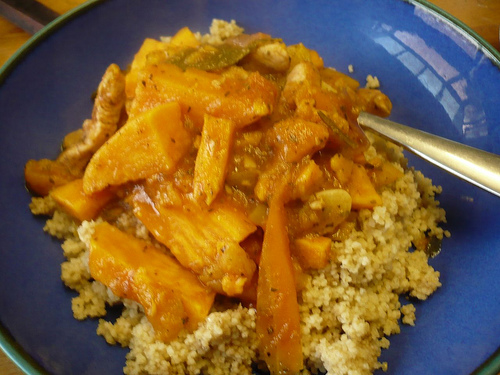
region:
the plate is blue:
[1, 0, 498, 372]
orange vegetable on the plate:
[38, 42, 398, 369]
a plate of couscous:
[3, 0, 499, 372]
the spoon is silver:
[363, 115, 498, 195]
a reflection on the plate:
[383, 23, 481, 136]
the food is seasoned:
[41, 19, 446, 371]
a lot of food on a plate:
[3, 0, 498, 372]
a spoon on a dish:
[352, 105, 494, 193]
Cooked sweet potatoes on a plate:
[31, 33, 408, 349]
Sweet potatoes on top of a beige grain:
[50, 21, 452, 374]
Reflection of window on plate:
[350, 7, 497, 146]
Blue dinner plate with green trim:
[0, 0, 494, 372]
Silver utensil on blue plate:
[341, 105, 498, 242]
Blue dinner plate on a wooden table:
[1, 0, 493, 371]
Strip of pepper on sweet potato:
[316, 109, 356, 153]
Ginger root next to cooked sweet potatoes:
[24, 67, 134, 185]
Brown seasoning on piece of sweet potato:
[260, 282, 284, 370]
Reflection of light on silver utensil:
[396, 128, 498, 193]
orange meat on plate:
[79, 25, 339, 295]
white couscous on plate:
[285, 195, 452, 357]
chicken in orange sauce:
[157, 72, 310, 232]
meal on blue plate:
[77, 60, 479, 350]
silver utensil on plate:
[362, 104, 499, 203]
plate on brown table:
[20, 20, 465, 327]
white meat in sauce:
[91, 77, 271, 271]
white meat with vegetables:
[53, 46, 410, 276]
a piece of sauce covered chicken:
[82, 220, 209, 320]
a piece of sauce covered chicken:
[133, 185, 248, 293]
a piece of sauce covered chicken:
[52, 180, 111, 219]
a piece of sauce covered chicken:
[82, 111, 193, 186]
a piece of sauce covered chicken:
[191, 111, 233, 203]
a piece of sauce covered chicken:
[132, 68, 269, 138]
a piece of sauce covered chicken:
[52, 63, 123, 183]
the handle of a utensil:
[359, 113, 499, 204]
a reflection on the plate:
[365, 16, 482, 137]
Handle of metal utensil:
[352, 107, 495, 199]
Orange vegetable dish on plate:
[23, 24, 407, 368]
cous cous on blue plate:
[31, 123, 443, 371]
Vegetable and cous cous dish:
[22, 30, 446, 372]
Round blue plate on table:
[2, 2, 498, 373]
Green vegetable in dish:
[171, 43, 247, 72]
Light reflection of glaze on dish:
[121, 134, 231, 229]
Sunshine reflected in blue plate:
[362, 1, 498, 138]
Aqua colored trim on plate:
[0, 2, 495, 370]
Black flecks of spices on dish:
[257, 274, 282, 361]